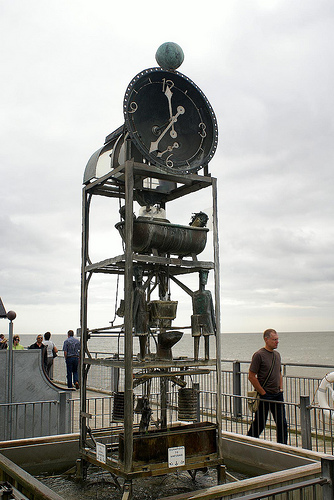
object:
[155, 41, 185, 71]
object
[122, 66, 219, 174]
clock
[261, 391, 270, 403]
hands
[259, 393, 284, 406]
pocket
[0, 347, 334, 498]
boat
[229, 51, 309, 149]
sky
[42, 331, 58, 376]
lady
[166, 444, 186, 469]
sign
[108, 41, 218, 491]
exhibit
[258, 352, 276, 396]
strap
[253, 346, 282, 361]
shoulder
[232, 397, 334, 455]
railing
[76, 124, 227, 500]
structure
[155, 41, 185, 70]
ball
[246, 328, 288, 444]
man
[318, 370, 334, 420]
preserver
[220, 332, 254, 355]
water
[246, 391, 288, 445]
pants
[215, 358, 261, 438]
fence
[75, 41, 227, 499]
tower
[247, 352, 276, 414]
bag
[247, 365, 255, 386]
elbow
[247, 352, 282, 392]
arm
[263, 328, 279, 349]
head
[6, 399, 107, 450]
enclosure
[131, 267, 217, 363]
statue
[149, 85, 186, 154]
hands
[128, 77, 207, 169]
number